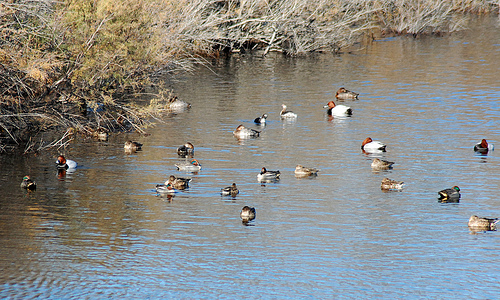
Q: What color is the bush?
A: Brown.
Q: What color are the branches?
A: Brown.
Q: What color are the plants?
A: Brown.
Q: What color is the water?
A: Blue.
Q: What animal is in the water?
A: Ducks.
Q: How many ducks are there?
A: 24.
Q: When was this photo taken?
A: During the daytime.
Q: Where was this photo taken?
A: At a pond.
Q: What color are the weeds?
A: Brown.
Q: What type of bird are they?
A: Ducks.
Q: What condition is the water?
A: Calm.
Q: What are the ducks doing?
A: Floating in the water.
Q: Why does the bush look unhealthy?
A: Appears too dry.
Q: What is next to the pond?
A: Tall grass.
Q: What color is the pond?
A: Brown.